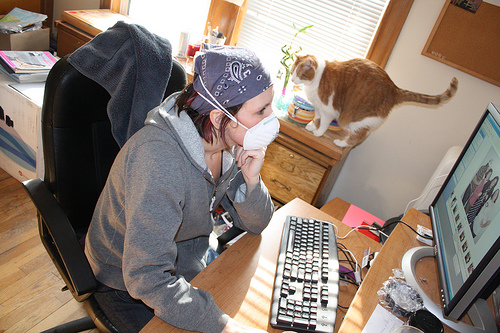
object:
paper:
[341, 203, 391, 245]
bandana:
[188, 48, 269, 115]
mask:
[194, 72, 281, 152]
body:
[317, 57, 395, 131]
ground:
[0, 248, 58, 333]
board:
[418, 0, 500, 90]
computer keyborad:
[267, 214, 339, 331]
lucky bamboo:
[276, 24, 315, 94]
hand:
[234, 142, 265, 176]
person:
[82, 41, 281, 333]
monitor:
[425, 100, 499, 322]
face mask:
[195, 75, 280, 152]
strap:
[191, 74, 245, 130]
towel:
[59, 21, 173, 148]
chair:
[19, 52, 187, 333]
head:
[288, 52, 322, 86]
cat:
[285, 53, 459, 149]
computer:
[265, 101, 499, 333]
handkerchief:
[183, 43, 273, 112]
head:
[177, 44, 281, 148]